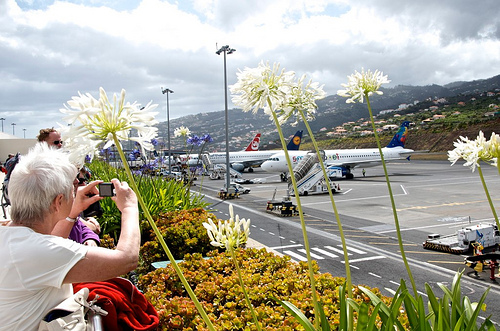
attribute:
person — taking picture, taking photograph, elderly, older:
[1, 140, 142, 330]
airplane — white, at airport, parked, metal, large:
[262, 123, 414, 184]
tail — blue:
[386, 119, 412, 148]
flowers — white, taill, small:
[339, 66, 429, 327]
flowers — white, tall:
[269, 70, 356, 330]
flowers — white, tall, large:
[225, 60, 327, 324]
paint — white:
[438, 214, 469, 224]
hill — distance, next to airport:
[88, 72, 499, 161]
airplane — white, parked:
[135, 130, 263, 175]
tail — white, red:
[244, 130, 261, 150]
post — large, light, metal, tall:
[213, 43, 235, 194]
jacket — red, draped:
[65, 274, 161, 330]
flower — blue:
[197, 133, 213, 145]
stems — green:
[191, 144, 208, 178]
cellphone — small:
[98, 177, 115, 198]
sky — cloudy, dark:
[2, 1, 500, 139]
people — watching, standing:
[36, 123, 62, 155]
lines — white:
[258, 178, 407, 205]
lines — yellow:
[398, 198, 480, 211]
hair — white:
[8, 140, 79, 224]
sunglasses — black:
[49, 139, 63, 144]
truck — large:
[291, 162, 344, 198]